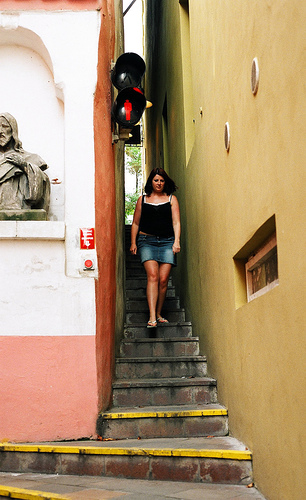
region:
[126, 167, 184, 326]
woman walking down the stairs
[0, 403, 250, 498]
yellow edges of stairs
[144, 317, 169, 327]
flip flops woman is wearing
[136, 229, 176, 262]
jean skirt woman is wearing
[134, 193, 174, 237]
black tank top of woman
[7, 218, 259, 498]
staircase woman is walking down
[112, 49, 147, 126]
black traffic signal attached to wall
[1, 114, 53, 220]
gray statute affixed to wall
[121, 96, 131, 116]
red outline of person traffic light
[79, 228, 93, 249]
red and white sign on building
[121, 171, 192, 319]
woman descending narrow staircase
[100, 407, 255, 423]
yellow edges on staircase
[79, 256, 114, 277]
red button on wall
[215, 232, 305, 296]
small window in wall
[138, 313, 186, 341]
white sandals on girl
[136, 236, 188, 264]
jean skirt on girl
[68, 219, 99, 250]
red sticker on wall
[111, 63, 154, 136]
black balloons above girl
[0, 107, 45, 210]
statue of Jesus on wall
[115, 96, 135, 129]
red logo of man on balloon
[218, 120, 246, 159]
white disc on yellow wall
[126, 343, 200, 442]
series of brown steps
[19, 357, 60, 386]
pink paint on wall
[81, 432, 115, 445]
small gold leaves on steps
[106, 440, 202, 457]
yellow edge on steps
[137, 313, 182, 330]
silver flip flops on feet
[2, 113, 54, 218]
silver statue on wall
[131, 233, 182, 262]
small blue jeans skirt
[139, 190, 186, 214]
white border on black shirt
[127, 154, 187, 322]
woman walking down red steps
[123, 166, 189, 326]
this is a lady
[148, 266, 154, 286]
the lady is light skinned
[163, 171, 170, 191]
this is the hair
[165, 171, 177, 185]
the hair is long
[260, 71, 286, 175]
this is the wall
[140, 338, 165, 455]
this is the stairs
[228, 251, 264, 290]
this is the window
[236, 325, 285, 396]
the wall is brown in color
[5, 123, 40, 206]
this is a statue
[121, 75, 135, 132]
this is a light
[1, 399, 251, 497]
Yellow paint on edge of steps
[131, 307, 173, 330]
Woman wearing flip flops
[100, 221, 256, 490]
Staircase between two buildings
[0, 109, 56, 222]
Stone figure inside window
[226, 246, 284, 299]
Small rectangular window in building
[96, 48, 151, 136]
Red pedestrian traffic light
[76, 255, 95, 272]
Red button on wall of building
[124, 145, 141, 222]
Green tree behind staircase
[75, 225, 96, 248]
Red and white sign on wall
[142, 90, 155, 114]
Lighted lamp behind traffic light